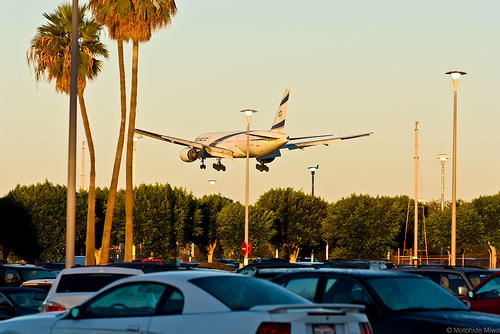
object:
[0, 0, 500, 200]
clouds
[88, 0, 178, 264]
palmtrees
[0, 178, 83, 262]
tree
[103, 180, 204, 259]
tree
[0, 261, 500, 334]
parking lot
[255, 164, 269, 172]
landing gear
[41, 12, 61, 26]
fronds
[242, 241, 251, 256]
sign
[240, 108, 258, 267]
pole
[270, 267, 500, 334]
car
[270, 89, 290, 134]
tail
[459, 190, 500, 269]
trees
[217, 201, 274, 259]
tree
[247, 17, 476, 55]
blue sky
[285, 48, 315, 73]
pale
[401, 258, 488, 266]
fence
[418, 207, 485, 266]
tree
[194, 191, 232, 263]
tree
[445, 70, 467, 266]
lamp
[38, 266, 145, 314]
car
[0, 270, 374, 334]
vehicle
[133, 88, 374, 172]
airplane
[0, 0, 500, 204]
sky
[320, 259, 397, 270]
vehicle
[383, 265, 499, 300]
vehicle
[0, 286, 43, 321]
vehicle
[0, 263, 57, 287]
vehicle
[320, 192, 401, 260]
tree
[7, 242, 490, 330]
lot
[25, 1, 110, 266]
tree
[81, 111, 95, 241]
trunk